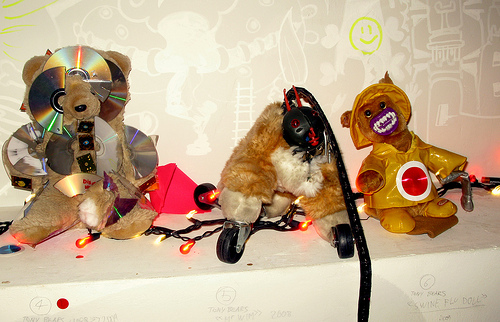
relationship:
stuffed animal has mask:
[242, 112, 351, 233] [291, 114, 315, 147]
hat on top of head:
[361, 91, 416, 117] [359, 106, 397, 135]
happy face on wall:
[347, 8, 391, 64] [7, 11, 499, 178]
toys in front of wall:
[26, 67, 471, 238] [7, 11, 499, 178]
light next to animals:
[295, 213, 324, 236] [214, 93, 470, 247]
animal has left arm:
[340, 90, 478, 248] [429, 146, 460, 179]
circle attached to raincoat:
[393, 163, 435, 201] [377, 155, 466, 208]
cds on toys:
[12, 61, 78, 176] [0, 39, 163, 253]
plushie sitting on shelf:
[225, 101, 346, 241] [22, 257, 493, 308]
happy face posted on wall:
[347, 8, 391, 64] [7, 11, 499, 178]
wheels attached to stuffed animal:
[221, 225, 357, 266] [242, 112, 351, 233]